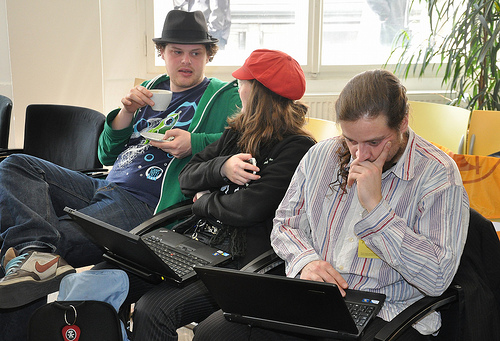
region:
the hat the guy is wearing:
[156, 13, 226, 71]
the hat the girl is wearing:
[233, 47, 311, 117]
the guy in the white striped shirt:
[299, 127, 481, 303]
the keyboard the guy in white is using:
[199, 265, 389, 328]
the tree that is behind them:
[387, 16, 499, 83]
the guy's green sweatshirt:
[111, 74, 233, 198]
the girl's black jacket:
[201, 114, 307, 248]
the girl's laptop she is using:
[69, 204, 234, 292]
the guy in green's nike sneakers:
[2, 248, 87, 331]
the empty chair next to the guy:
[28, 104, 127, 193]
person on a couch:
[190, 61, 465, 339]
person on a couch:
[57, 38, 335, 339]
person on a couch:
[0, 3, 245, 315]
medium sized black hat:
[142, 2, 226, 58]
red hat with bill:
[225, 45, 314, 102]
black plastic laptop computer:
[189, 259, 389, 336]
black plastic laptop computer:
[56, 198, 234, 290]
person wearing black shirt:
[57, 37, 332, 339]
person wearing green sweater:
[0, 2, 262, 312]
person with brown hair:
[197, 71, 477, 339]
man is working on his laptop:
[271, 110, 410, 313]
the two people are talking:
[162, 18, 280, 133]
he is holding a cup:
[141, 19, 188, 161]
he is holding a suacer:
[131, 18, 187, 152]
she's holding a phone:
[215, 148, 267, 191]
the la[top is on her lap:
[74, 184, 219, 293]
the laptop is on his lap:
[211, 251, 368, 335]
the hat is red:
[233, 36, 303, 106]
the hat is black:
[148, 14, 221, 43]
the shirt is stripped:
[313, 165, 370, 246]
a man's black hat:
[150, 10, 215, 47]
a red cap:
[230, 43, 310, 100]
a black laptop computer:
[54, 197, 231, 289]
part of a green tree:
[395, 0, 498, 109]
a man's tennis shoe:
[0, 240, 79, 310]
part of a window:
[155, 3, 307, 68]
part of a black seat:
[19, 100, 106, 174]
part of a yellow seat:
[405, 98, 469, 151]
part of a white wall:
[10, 3, 101, 108]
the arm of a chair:
[381, 283, 461, 339]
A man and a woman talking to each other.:
[6, 6, 318, 330]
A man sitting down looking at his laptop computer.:
[194, 72, 474, 336]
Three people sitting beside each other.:
[0, 9, 497, 339]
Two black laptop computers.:
[61, 204, 388, 339]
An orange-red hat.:
[234, 49, 308, 99]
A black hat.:
[154, 10, 218, 49]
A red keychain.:
[61, 301, 81, 339]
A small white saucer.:
[140, 128, 175, 139]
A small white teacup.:
[144, 86, 172, 114]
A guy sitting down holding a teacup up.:
[0, 10, 242, 316]